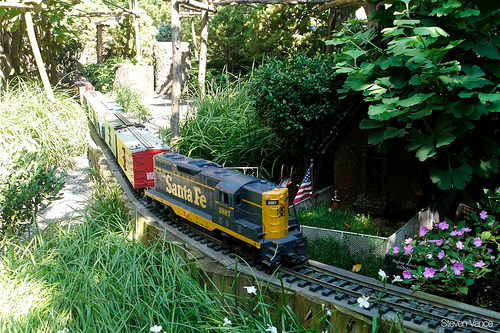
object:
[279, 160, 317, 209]
flag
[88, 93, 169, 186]
middle part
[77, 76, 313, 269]
train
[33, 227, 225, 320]
grass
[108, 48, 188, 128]
sunlight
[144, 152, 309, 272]
engine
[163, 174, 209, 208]
santa fe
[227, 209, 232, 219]
number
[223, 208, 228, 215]
number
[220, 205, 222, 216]
number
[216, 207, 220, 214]
number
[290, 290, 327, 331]
brick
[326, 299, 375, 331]
brick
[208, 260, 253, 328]
brick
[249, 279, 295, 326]
brick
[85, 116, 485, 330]
track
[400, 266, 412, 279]
flower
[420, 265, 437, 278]
flower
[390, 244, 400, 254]
flower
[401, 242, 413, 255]
flower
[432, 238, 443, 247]
flower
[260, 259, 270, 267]
step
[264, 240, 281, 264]
step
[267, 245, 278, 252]
step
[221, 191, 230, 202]
window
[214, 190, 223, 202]
window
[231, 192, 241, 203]
window